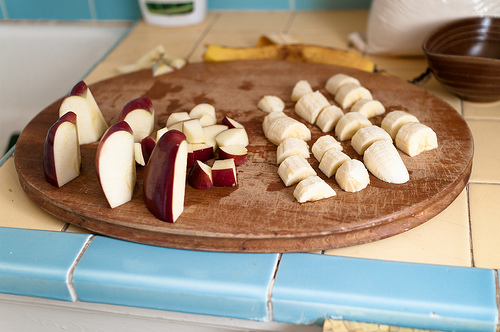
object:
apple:
[42, 111, 81, 189]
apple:
[58, 80, 109, 146]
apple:
[95, 120, 137, 209]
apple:
[143, 129, 187, 223]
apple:
[211, 158, 238, 188]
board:
[13, 59, 474, 253]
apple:
[218, 146, 248, 165]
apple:
[182, 118, 206, 144]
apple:
[222, 116, 244, 129]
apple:
[166, 111, 188, 128]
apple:
[186, 159, 213, 189]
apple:
[189, 101, 215, 121]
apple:
[133, 142, 146, 166]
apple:
[139, 135, 157, 167]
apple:
[187, 143, 214, 168]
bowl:
[422, 15, 500, 104]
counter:
[0, 9, 499, 332]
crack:
[405, 63, 434, 88]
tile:
[1, 227, 92, 303]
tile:
[71, 234, 280, 323]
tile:
[271, 252, 497, 332]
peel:
[203, 32, 374, 75]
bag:
[346, 0, 500, 60]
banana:
[293, 176, 337, 203]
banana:
[277, 155, 317, 187]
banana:
[350, 125, 393, 155]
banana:
[395, 123, 438, 157]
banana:
[311, 134, 343, 161]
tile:
[322, 183, 471, 267]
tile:
[465, 183, 499, 270]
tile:
[0, 153, 65, 232]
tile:
[211, 10, 290, 39]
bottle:
[138, 0, 206, 27]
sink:
[0, 21, 130, 166]